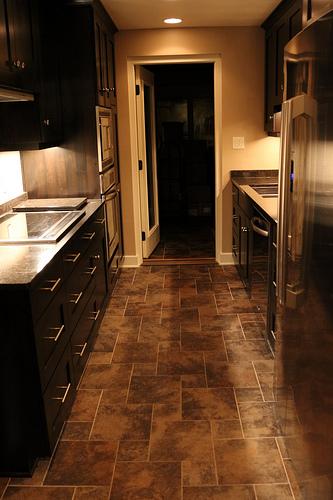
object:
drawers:
[62, 233, 85, 279]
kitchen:
[0, 0, 333, 499]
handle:
[39, 277, 61, 292]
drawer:
[27, 252, 66, 328]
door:
[130, 63, 160, 259]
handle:
[250, 217, 269, 237]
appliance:
[247, 203, 276, 356]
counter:
[0, 189, 115, 480]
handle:
[275, 92, 319, 310]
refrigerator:
[274, 10, 332, 480]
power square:
[232, 136, 244, 149]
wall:
[115, 27, 283, 268]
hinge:
[133, 64, 147, 260]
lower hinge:
[141, 231, 146, 243]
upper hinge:
[136, 84, 140, 96]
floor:
[108, 308, 259, 497]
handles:
[13, 59, 28, 72]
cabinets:
[0, 0, 77, 155]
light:
[290, 172, 296, 186]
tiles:
[134, 269, 220, 323]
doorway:
[133, 61, 215, 265]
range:
[0, 207, 86, 245]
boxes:
[188, 203, 213, 236]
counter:
[230, 168, 282, 360]